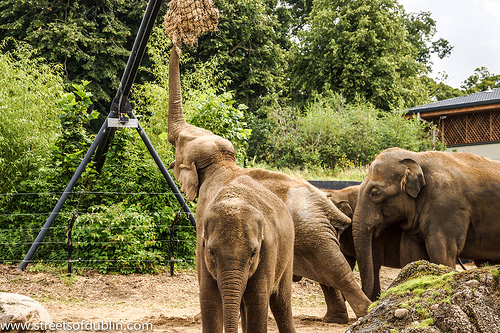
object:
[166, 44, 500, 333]
elephants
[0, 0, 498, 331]
enclosure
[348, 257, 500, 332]
moss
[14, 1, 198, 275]
tripod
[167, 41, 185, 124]
trunk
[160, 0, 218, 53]
nuts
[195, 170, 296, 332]
elephant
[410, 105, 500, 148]
panel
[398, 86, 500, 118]
roof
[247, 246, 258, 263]
dark eye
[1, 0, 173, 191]
tree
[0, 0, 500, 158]
trees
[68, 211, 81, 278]
poles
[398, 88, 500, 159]
house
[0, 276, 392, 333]
dirt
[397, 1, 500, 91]
sky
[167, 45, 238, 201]
elephant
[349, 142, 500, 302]
elephant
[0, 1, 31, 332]
left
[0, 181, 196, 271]
fence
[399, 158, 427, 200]
ear